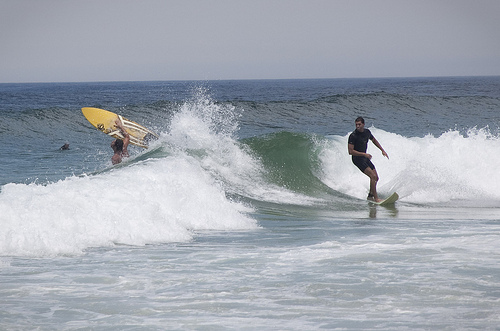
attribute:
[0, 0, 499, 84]
sky — blue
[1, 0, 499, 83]
clouds — white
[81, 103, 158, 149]
surfboard — bright yellow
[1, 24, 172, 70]
cloud — white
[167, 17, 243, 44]
clouds — white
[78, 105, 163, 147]
board — falling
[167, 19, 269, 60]
clouds — white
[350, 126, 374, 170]
wetsuit — black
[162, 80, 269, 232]
wave — crashing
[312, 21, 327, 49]
clouds — white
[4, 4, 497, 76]
clouds — white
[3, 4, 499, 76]
sky — blue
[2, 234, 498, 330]
foam — white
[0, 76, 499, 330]
water — ocean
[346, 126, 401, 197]
wetsuit — black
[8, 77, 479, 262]
wave — crashing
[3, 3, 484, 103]
sky — blue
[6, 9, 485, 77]
clouds — white